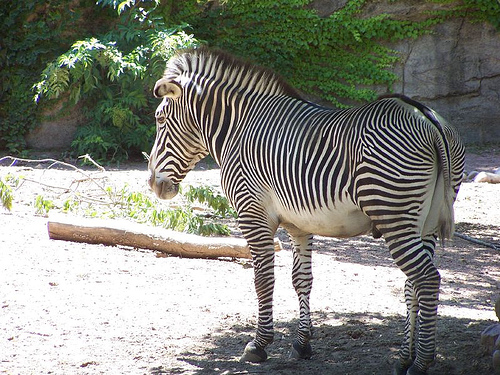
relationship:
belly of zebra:
[281, 194, 367, 243] [117, 34, 484, 357]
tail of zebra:
[433, 122, 463, 244] [152, 51, 454, 368]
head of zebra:
[127, 37, 217, 201] [122, 47, 473, 373]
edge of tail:
[440, 169, 449, 184] [424, 100, 449, 222]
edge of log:
[180, 251, 214, 263] [46, 220, 260, 260]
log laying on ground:
[45, 208, 283, 257] [33, 266, 189, 361]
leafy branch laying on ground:
[32, 142, 207, 234] [115, 286, 163, 348]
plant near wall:
[16, 36, 148, 168] [23, 0, 497, 166]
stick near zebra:
[445, 224, 495, 249] [116, 57, 423, 254]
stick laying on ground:
[445, 224, 495, 249] [3, 140, 498, 373]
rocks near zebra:
[469, 305, 499, 372] [142, 60, 467, 360]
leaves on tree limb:
[4, 180, 218, 238] [0, 152, 244, 239]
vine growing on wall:
[206, 0, 432, 103] [7, 2, 492, 175]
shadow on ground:
[154, 305, 499, 370] [3, 140, 498, 373]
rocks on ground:
[459, 163, 498, 184] [3, 140, 498, 373]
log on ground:
[47, 216, 283, 259] [3, 140, 498, 373]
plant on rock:
[53, 28, 151, 135] [18, 85, 112, 162]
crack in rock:
[423, 94, 482, 107] [385, 25, 492, 168]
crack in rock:
[470, 75, 497, 82] [385, 25, 492, 168]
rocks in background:
[463, 157, 498, 187] [210, 7, 498, 90]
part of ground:
[54, 274, 139, 372] [3, 140, 498, 373]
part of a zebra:
[257, 130, 310, 174] [122, 47, 473, 373]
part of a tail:
[440, 136, 458, 235] [437, 142, 464, 256]